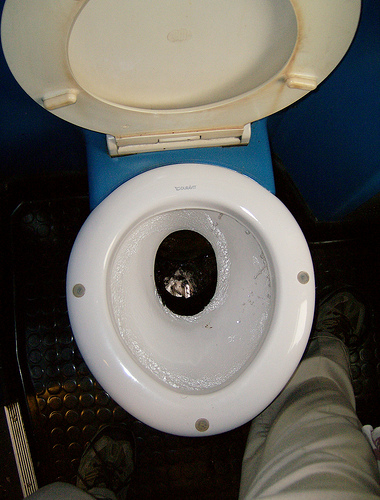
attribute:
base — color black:
[147, 229, 226, 321]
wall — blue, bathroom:
[9, 63, 371, 235]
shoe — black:
[306, 281, 369, 359]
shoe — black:
[69, 419, 141, 498]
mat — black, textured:
[14, 298, 159, 498]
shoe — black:
[312, 287, 368, 347]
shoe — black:
[73, 421, 137, 495]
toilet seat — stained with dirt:
[10, 0, 327, 159]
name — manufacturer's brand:
[171, 182, 200, 194]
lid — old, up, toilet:
[0, 0, 360, 157]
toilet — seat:
[46, 138, 331, 462]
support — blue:
[86, 131, 277, 188]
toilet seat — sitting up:
[20, 31, 366, 171]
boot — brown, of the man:
[318, 266, 376, 356]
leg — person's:
[237, 344, 375, 498]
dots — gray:
[293, 270, 310, 287]